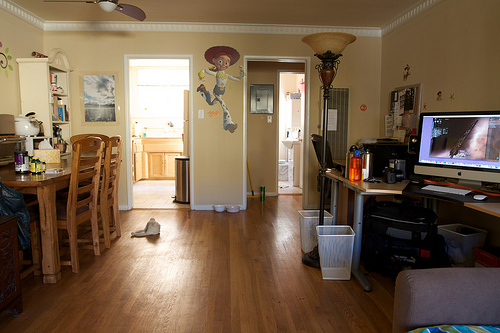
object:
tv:
[413, 111, 500, 182]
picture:
[83, 75, 115, 123]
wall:
[1, 0, 499, 210]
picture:
[197, 46, 244, 133]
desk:
[0, 152, 123, 284]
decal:
[197, 46, 244, 133]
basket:
[315, 225, 355, 280]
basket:
[297, 210, 333, 254]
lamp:
[301, 31, 356, 268]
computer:
[414, 111, 500, 197]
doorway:
[242, 55, 311, 210]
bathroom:
[275, 66, 306, 197]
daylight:
[127, 58, 190, 139]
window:
[130, 59, 188, 129]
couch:
[390, 267, 499, 332]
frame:
[124, 55, 195, 210]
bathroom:
[278, 72, 303, 194]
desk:
[325, 160, 499, 293]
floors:
[1, 179, 396, 332]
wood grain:
[27, 196, 382, 333]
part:
[181, 209, 221, 256]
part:
[258, 209, 296, 256]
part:
[26, 287, 69, 331]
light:
[278, 72, 305, 117]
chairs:
[56, 133, 122, 273]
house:
[0, 0, 499, 333]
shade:
[301, 32, 357, 57]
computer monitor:
[414, 111, 500, 173]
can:
[173, 156, 191, 204]